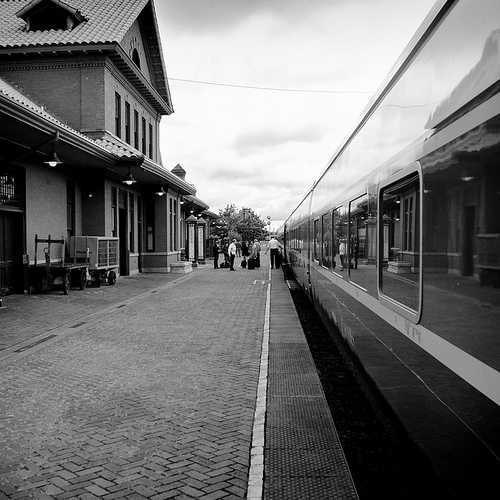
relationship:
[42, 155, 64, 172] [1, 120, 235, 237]
light under awning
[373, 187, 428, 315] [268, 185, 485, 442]
window of train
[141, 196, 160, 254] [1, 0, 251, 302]
window of a building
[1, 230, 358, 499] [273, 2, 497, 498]
road near train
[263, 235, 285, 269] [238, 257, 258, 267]
man putting luggage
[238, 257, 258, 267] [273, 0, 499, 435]
luggage on train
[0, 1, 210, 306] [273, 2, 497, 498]
building reflecting on train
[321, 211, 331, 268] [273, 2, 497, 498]
window of train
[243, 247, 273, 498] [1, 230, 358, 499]
line on road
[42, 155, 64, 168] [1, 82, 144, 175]
light under awning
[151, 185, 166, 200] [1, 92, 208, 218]
light under awning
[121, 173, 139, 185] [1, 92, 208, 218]
light under awning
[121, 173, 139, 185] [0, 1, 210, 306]
light on building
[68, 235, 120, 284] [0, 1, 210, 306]
cart near building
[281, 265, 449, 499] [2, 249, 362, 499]
gap between platform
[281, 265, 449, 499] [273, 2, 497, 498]
gap between train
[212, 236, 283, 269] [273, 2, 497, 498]
people on train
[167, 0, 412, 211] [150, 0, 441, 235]
clouds in sky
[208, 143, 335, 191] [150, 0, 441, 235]
clouds in sky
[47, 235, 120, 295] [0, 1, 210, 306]
cart near building